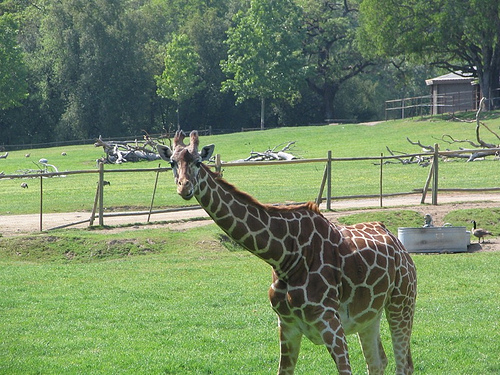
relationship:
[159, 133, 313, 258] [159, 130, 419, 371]
neck of giraffe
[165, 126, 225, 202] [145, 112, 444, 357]
head on a giraffe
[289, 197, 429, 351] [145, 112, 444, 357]
body of a giraffe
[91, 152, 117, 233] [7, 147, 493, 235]
wood and metal fence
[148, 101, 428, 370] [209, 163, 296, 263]
giraffe with neck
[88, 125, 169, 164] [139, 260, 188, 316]
branches and logs in piles on grass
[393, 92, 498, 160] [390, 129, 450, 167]
trunk with curved branches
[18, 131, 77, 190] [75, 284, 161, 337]
birds walking on grass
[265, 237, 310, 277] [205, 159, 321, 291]
wrinkles at base of neck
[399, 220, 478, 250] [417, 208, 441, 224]
metal trough with some birds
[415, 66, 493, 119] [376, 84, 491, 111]
building surrounded by a fence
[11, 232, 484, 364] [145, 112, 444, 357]
field that giraffe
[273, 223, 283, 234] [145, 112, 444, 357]
brown spot on giraffe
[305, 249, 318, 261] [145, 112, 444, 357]
brown spot on giraffe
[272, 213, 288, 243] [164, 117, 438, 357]
brown spot on giraffe